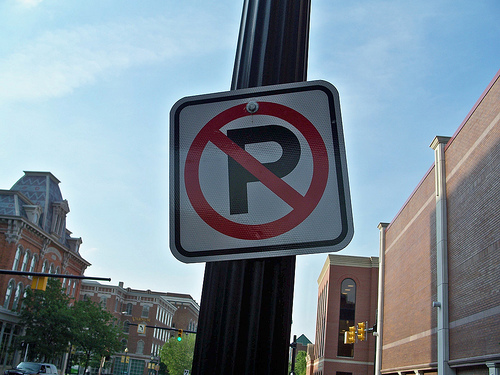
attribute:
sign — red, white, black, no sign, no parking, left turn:
[170, 79, 355, 264]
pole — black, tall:
[189, 1, 314, 372]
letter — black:
[227, 123, 300, 216]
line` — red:
[211, 130, 304, 209]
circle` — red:
[185, 102, 327, 240]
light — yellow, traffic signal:
[348, 323, 354, 343]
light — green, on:
[176, 335, 182, 341]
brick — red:
[377, 69, 499, 369]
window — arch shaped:
[337, 276, 358, 356]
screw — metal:
[247, 100, 259, 114]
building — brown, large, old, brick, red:
[314, 255, 379, 374]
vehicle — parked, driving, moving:
[9, 361, 60, 374]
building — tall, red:
[2, 169, 91, 374]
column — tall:
[428, 136, 455, 374]